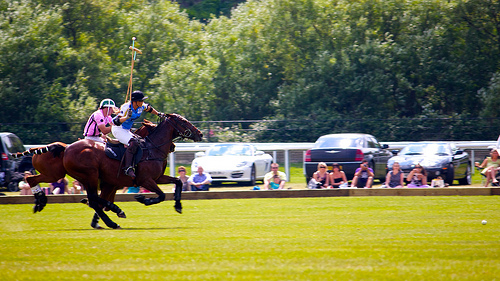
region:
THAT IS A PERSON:
[266, 156, 294, 195]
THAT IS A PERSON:
[307, 155, 326, 189]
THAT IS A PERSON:
[331, 163, 342, 179]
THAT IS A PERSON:
[348, 153, 373, 190]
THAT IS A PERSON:
[386, 155, 399, 186]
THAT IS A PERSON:
[403, 161, 423, 186]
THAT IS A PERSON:
[429, 159, 441, 190]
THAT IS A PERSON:
[474, 145, 496, 192]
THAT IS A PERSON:
[80, 94, 122, 143]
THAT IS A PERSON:
[121, 84, 149, 133]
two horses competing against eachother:
[31, 90, 206, 228]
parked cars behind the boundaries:
[183, 132, 473, 183]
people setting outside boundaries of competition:
[15, 146, 495, 181]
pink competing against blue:
[80, 85, 155, 140]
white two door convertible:
[194, 140, 273, 185]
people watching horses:
[0, 146, 495, 191]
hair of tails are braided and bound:
[2, 142, 52, 154]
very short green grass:
[0, 195, 497, 277]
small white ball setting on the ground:
[480, 216, 485, 221]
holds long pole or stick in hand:
[122, 35, 137, 117]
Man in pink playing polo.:
[82, 98, 117, 145]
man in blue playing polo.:
[109, 90, 163, 180]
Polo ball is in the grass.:
[481, 218, 487, 224]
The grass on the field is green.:
[0, 194, 499, 279]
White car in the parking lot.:
[191, 139, 272, 181]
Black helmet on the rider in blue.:
[131, 91, 148, 101]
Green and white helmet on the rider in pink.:
[100, 98, 115, 107]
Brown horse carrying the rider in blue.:
[62, 110, 202, 228]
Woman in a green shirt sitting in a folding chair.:
[475, 148, 499, 185]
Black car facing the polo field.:
[386, 143, 473, 182]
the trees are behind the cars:
[78, 25, 357, 195]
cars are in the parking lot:
[184, 120, 465, 213]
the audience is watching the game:
[258, 145, 497, 251]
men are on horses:
[77, 75, 189, 236]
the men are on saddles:
[72, 78, 207, 212]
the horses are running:
[15, 130, 193, 240]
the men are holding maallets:
[86, 41, 283, 252]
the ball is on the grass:
[452, 190, 493, 262]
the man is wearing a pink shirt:
[66, 93, 119, 171]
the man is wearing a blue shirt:
[114, 93, 180, 143]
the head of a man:
[93, 88, 125, 123]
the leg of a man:
[107, 108, 161, 174]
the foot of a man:
[114, 163, 144, 193]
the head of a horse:
[161, 85, 223, 145]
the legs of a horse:
[136, 166, 211, 231]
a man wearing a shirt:
[80, 93, 127, 142]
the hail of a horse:
[21, 129, 96, 179]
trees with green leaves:
[246, 0, 416, 132]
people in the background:
[281, 88, 468, 191]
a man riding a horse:
[64, 58, 244, 257]